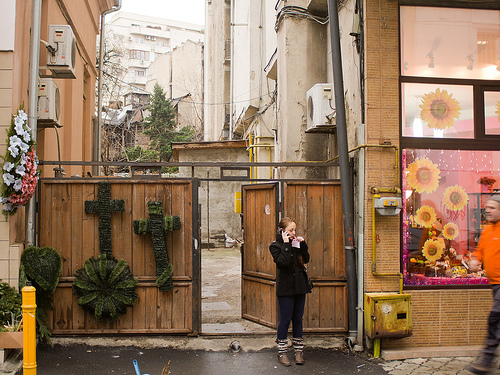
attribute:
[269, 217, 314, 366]
woman — standing, talking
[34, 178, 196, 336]
wall — wood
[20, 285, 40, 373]
pole — yellow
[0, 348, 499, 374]
street — paved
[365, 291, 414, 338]
gas meter — yellow, rusty, utility box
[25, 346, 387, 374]
pavement — black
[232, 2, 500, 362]
building — store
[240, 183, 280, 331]
gate — wooden, open, wood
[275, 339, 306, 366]
boots — brown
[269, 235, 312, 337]
clothes — black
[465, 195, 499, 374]
man — walking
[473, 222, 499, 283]
sweatshirt — orange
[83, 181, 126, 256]
cross — brown, artwork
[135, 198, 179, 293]
cross — brown, artwork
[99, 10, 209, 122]
building — tall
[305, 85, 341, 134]
fan — white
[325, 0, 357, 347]
pipe — black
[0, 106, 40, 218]
flower — hanging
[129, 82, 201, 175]
tree — large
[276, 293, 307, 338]
pants — blue